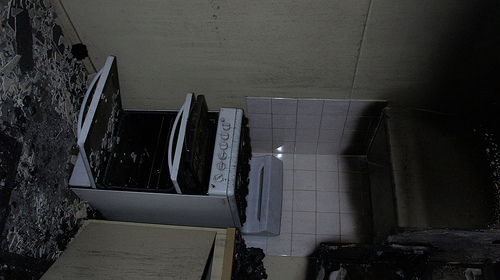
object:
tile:
[248, 96, 355, 151]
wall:
[246, 94, 272, 113]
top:
[235, 106, 252, 227]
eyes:
[235, 110, 255, 220]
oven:
[77, 72, 279, 221]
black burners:
[237, 128, 262, 224]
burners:
[236, 122, 263, 212]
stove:
[58, 59, 294, 206]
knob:
[186, 123, 248, 158]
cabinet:
[313, 200, 445, 279]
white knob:
[217, 139, 231, 151]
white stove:
[68, 55, 287, 235]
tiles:
[36, 8, 90, 65]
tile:
[314, 169, 339, 191]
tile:
[316, 190, 338, 210]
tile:
[292, 169, 315, 188]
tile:
[291, 188, 321, 211]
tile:
[290, 233, 316, 255]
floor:
[5, 4, 94, 274]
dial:
[221, 123, 229, 130]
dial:
[219, 132, 229, 139]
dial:
[218, 141, 227, 148]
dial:
[217, 151, 227, 160]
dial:
[217, 161, 225, 169]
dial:
[213, 172, 224, 182]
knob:
[219, 119, 238, 132]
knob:
[212, 172, 223, 183]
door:
[74, 55, 130, 192]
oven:
[62, 70, 273, 232]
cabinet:
[21, 210, 241, 279]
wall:
[242, 100, 409, 262]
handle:
[69, 59, 110, 136]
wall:
[358, 0, 478, 100]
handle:
[167, 103, 184, 172]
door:
[166, 90, 195, 194]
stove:
[85, 70, 234, 207]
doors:
[199, 191, 286, 231]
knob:
[215, 150, 240, 163]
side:
[70, 189, 235, 229]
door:
[30, 220, 217, 279]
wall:
[0, 2, 498, 154]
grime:
[53, 0, 478, 101]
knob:
[220, 130, 229, 139]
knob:
[219, 140, 229, 149]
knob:
[219, 148, 226, 159]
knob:
[217, 157, 226, 171]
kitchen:
[0, 4, 499, 276]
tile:
[2, 3, 99, 275]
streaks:
[50, 241, 221, 279]